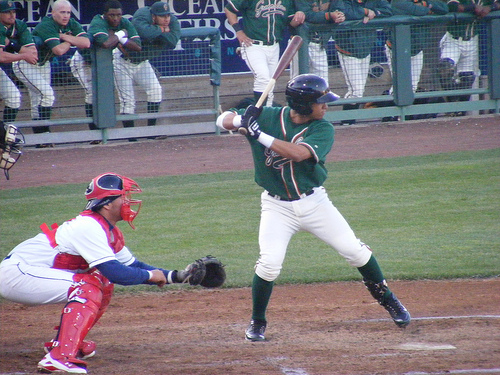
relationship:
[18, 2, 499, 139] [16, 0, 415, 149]
players in dugout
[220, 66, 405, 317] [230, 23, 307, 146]
player swinging bat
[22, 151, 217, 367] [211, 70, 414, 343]
catcher looking at player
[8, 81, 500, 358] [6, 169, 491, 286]
field has grass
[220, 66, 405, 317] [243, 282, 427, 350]
player has cleets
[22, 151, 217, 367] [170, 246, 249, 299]
catcher has mitt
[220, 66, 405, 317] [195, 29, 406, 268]
man plays baseball.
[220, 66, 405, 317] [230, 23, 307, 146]
player has bat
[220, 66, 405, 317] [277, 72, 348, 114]
player wears helmet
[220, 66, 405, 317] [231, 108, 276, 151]
player wears gloves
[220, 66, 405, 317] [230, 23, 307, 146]
player holds bat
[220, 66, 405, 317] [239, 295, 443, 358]
player wears shoes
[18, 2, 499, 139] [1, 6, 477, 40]
players wear jerseys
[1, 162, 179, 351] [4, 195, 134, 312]
player wears white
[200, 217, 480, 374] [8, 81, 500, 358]
homeplate on field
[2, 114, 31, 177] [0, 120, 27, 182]
umpire has umpire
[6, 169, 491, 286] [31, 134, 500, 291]
grass has patch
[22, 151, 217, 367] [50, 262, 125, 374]
catcher has leg protection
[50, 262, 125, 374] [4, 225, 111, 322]
leg protection for legs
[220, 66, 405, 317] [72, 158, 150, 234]
man has helmet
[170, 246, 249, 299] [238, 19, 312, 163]
glove for baseball